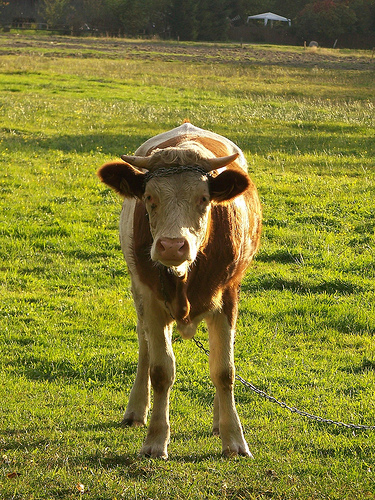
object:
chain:
[189, 332, 369, 442]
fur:
[105, 168, 127, 187]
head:
[96, 146, 253, 277]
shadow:
[10, 345, 138, 387]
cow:
[96, 119, 263, 459]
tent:
[245, 11, 291, 42]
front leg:
[139, 307, 176, 459]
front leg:
[209, 308, 252, 458]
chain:
[141, 163, 212, 187]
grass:
[1, 32, 363, 496]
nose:
[157, 237, 188, 258]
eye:
[146, 194, 152, 200]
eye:
[200, 194, 208, 203]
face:
[147, 167, 211, 259]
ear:
[96, 159, 145, 199]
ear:
[208, 167, 251, 203]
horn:
[120, 155, 150, 170]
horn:
[205, 151, 239, 173]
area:
[2, 4, 374, 497]